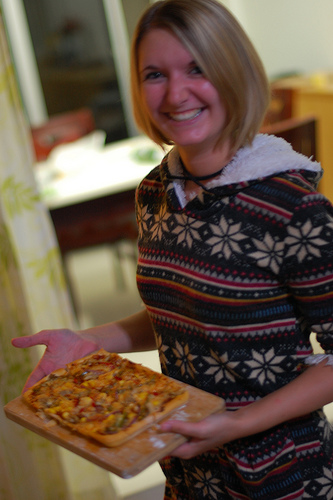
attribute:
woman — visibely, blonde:
[90, 37, 306, 380]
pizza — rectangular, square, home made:
[60, 361, 166, 424]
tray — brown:
[14, 338, 215, 496]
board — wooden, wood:
[18, 346, 192, 497]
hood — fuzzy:
[234, 122, 333, 206]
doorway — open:
[13, 8, 138, 142]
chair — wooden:
[34, 115, 102, 144]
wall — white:
[264, 16, 319, 54]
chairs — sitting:
[19, 116, 112, 184]